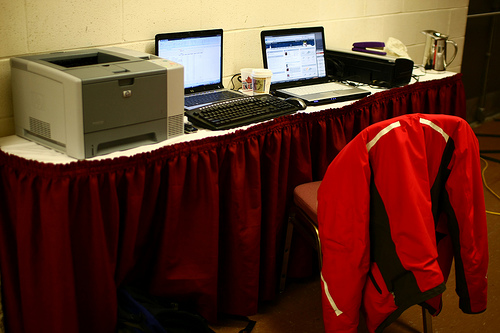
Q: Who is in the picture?
A: No one.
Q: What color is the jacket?
A: Red and black.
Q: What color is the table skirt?
A: Red.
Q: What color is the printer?
A: Gray.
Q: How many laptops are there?
A: 2.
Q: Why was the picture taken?
A: To show the work area.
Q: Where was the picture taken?
A: At a work area.